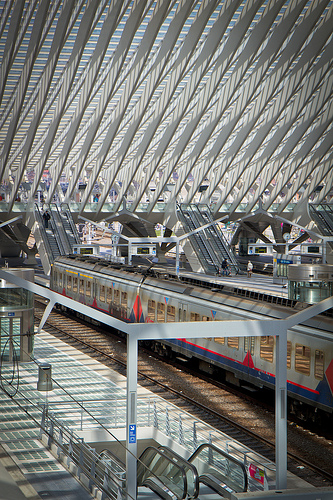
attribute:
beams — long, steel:
[7, 5, 328, 218]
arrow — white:
[127, 423, 137, 433]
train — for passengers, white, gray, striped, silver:
[49, 253, 330, 408]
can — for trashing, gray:
[38, 361, 53, 392]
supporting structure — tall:
[123, 319, 141, 500]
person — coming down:
[43, 209, 53, 230]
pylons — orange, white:
[244, 460, 269, 494]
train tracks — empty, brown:
[30, 294, 331, 493]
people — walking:
[220, 259, 254, 278]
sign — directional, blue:
[129, 422, 138, 444]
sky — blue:
[1, 5, 330, 166]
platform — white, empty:
[16, 308, 258, 448]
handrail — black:
[100, 446, 187, 495]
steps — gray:
[45, 226, 64, 269]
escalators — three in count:
[33, 199, 331, 282]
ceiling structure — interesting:
[10, 6, 332, 214]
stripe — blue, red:
[82, 305, 322, 403]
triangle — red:
[248, 353, 257, 372]